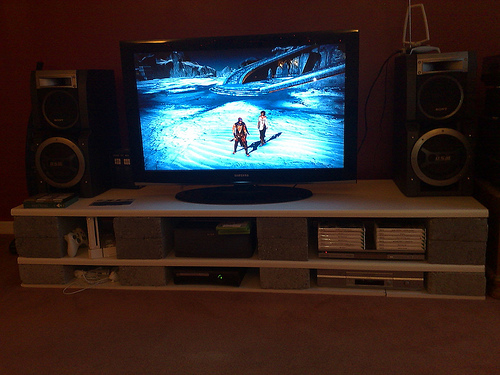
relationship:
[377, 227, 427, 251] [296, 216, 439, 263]
cd on cubby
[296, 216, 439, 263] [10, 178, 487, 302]
cubby in cabinet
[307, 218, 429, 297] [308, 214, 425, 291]
video game on shelf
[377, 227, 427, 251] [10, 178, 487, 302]
cd on cabinet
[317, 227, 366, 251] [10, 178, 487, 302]
cd on cabinet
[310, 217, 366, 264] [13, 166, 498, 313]
cd on stand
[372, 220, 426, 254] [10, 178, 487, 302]
cd in cabinet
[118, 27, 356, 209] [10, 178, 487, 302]
television on cabinet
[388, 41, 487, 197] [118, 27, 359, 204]
speaker beside tv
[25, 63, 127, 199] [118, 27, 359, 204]
speaker beside tv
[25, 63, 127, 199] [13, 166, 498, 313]
speaker on stand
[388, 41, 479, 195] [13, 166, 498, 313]
speaker on stand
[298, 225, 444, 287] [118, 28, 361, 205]
dvds under television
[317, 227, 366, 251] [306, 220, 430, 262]
cd on a cuby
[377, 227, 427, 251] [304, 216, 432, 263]
cd on cubby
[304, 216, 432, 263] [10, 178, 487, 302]
cubby in cabinet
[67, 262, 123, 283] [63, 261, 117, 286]
controllers with wires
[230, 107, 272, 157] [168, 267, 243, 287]
characters on game